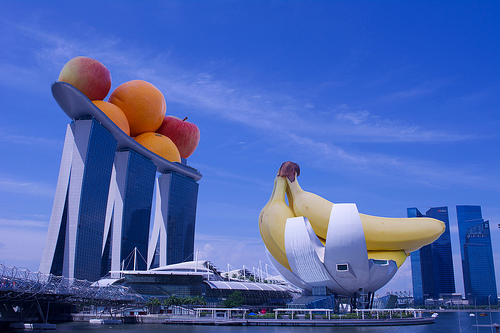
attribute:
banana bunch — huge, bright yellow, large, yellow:
[259, 159, 443, 279]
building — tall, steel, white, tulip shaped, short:
[271, 203, 395, 300]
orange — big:
[110, 81, 166, 132]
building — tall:
[46, 79, 202, 284]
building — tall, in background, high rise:
[408, 201, 456, 307]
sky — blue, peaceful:
[1, 3, 495, 298]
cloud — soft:
[31, 21, 475, 196]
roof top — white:
[282, 213, 330, 290]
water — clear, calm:
[2, 284, 499, 332]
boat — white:
[430, 310, 439, 320]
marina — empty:
[377, 302, 492, 330]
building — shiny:
[152, 169, 198, 267]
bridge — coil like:
[3, 268, 134, 320]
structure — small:
[258, 307, 266, 316]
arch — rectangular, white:
[207, 274, 296, 295]